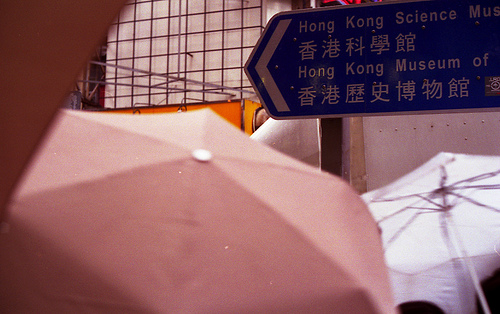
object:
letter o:
[308, 68, 316, 77]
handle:
[444, 210, 494, 314]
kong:
[346, 61, 385, 77]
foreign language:
[395, 9, 458, 24]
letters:
[318, 67, 325, 77]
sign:
[243, 0, 500, 120]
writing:
[294, 4, 500, 107]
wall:
[104, 0, 318, 109]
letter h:
[299, 65, 307, 78]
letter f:
[483, 53, 490, 67]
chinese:
[299, 40, 318, 61]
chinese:
[297, 86, 316, 107]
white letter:
[318, 21, 326, 31]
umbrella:
[356, 150, 499, 314]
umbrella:
[0, 105, 400, 313]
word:
[298, 66, 334, 80]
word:
[395, 58, 462, 71]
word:
[473, 49, 488, 68]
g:
[326, 66, 334, 80]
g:
[327, 21, 335, 34]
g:
[375, 64, 384, 77]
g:
[375, 16, 383, 29]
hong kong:
[298, 61, 385, 79]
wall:
[318, 0, 500, 198]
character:
[309, 22, 317, 32]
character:
[409, 61, 417, 70]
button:
[190, 149, 213, 163]